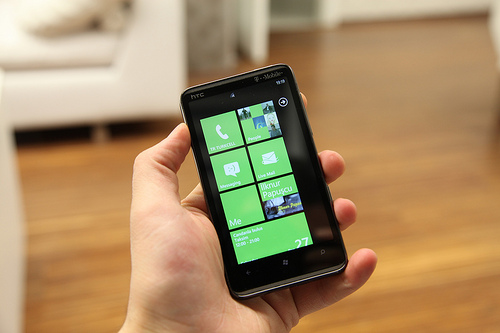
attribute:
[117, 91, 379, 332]
hand — white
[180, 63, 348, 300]
phone — rectangular, black, on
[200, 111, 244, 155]
square — green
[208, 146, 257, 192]
square — green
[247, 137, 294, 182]
square — green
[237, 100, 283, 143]
square — green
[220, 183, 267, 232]
square — green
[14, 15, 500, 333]
floor — wooden, light brown, hardwood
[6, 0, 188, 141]
couch — white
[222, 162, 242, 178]
icon — white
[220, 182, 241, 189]
texting — white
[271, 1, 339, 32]
door — white, open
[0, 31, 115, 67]
pillow — white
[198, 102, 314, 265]
menu — green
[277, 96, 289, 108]
arrow — little, white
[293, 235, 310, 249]
number — 27